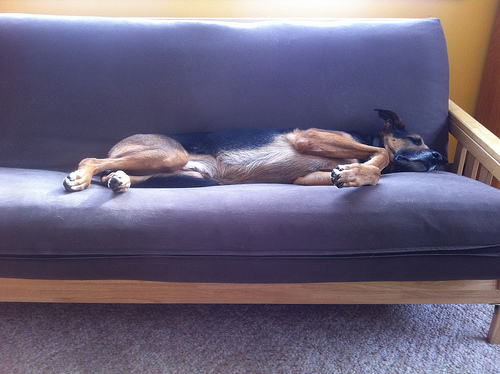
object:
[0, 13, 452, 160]
back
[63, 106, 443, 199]
dog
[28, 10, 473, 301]
couch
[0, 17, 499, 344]
couch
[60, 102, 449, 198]
german shepard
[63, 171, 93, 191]
paw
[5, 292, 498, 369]
carpet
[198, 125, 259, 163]
fur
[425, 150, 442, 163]
black nose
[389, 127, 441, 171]
face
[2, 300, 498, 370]
carpet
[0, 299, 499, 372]
floor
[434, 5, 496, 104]
yellow wall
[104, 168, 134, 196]
paw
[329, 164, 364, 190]
paw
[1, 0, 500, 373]
room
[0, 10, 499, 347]
sofa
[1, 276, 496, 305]
frame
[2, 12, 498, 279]
cushion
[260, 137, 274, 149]
spot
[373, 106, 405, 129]
ear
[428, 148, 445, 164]
nose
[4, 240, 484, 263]
line